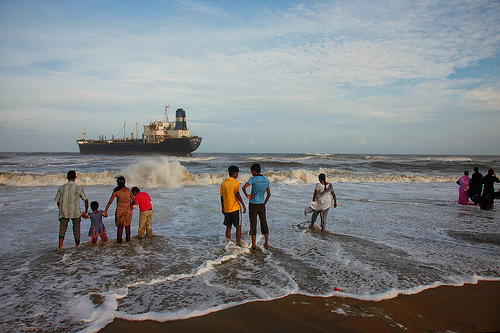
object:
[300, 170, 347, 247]
woman water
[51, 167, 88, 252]
person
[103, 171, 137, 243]
person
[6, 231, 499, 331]
beach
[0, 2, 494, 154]
overcast sky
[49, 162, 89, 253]
man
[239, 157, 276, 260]
boy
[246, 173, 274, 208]
blue shirt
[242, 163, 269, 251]
person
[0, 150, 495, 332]
water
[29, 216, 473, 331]
shore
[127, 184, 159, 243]
person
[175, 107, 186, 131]
smokestack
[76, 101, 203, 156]
ship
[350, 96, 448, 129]
cloud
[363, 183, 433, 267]
ocean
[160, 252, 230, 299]
water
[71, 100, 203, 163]
tanker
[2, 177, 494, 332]
shore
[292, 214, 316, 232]
net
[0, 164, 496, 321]
surf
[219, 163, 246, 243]
person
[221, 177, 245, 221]
shirt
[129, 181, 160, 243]
shirt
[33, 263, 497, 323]
shore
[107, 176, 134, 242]
woman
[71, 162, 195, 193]
water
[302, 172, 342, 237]
woman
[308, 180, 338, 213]
shirt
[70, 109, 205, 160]
tanker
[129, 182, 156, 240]
child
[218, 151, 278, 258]
friends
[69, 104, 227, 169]
tanker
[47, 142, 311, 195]
surf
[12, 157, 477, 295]
water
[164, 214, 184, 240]
part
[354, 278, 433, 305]
edge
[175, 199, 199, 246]
part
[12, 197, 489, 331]
beach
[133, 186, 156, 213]
red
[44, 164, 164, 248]
family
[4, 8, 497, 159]
sky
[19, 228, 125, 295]
water